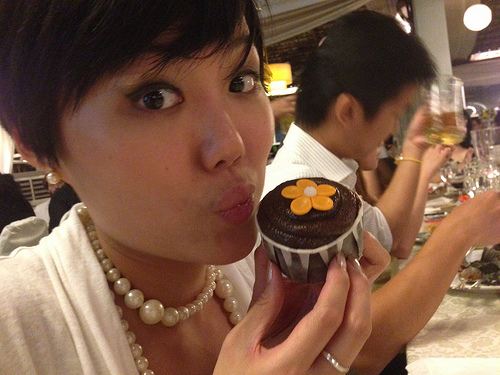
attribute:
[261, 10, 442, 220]
shirt — button-down, white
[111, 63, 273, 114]
eyes — almond shaped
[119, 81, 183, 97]
eye shadow — brown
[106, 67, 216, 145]
eye — brown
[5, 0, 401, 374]
woman — holding, brown, dark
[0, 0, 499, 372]
people — young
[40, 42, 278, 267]
face — young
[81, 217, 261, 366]
necklace — pearl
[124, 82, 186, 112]
eye — open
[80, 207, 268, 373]
necklace — pearl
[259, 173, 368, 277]
cake — chocolate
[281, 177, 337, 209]
flower decoration — orange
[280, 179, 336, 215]
flower — candied, orange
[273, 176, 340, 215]
frosting — orange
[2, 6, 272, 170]
hair — short, dark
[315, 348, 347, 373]
ring — silver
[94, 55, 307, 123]
eye — open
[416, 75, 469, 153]
mug beer — light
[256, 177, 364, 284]
cupcake — small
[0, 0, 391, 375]
young woman — holding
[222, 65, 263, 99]
eye — brown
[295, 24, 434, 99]
brown hair — dark brown, short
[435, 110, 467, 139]
liquid — amber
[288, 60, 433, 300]
man — young